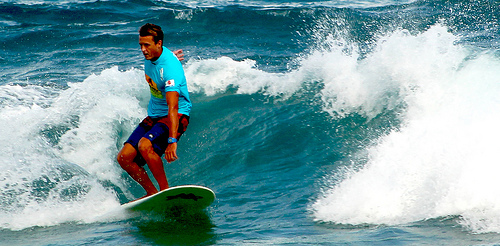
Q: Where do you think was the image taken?
A: It was taken at the ocean.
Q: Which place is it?
A: It is an ocean.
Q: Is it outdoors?
A: Yes, it is outdoors.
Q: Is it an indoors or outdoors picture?
A: It is outdoors.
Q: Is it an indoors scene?
A: No, it is outdoors.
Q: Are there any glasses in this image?
A: No, there are no glasses.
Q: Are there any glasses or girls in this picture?
A: No, there are no glasses or girls.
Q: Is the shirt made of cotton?
A: Yes, the shirt is made of cotton.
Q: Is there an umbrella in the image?
A: No, there are no umbrellas.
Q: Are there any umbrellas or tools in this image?
A: No, there are no umbrellas or tools.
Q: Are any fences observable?
A: No, there are no fences.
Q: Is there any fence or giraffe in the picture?
A: No, there are no fences or giraffes.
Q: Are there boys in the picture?
A: No, there are no boys.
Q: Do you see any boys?
A: No, there are no boys.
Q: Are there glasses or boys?
A: No, there are no boys or glasses.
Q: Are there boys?
A: No, there are no boys.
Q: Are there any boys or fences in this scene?
A: No, there are no boys or fences.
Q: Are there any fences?
A: No, there are no fences.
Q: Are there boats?
A: No, there are no boats.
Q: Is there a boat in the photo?
A: No, there are no boats.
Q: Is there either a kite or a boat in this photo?
A: No, there are no boats or kites.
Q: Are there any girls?
A: No, there are no girls.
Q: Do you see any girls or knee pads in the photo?
A: No, there are no girls or knee pads.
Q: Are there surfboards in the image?
A: Yes, there is a surfboard.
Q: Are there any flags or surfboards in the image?
A: Yes, there is a surfboard.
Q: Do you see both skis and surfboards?
A: No, there is a surfboard but no skis.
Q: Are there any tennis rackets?
A: No, there are no tennis rackets.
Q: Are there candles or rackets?
A: No, there are no rackets or candles.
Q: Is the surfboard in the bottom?
A: Yes, the surfboard is in the bottom of the image.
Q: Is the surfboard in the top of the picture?
A: No, the surfboard is in the bottom of the image.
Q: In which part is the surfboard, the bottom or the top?
A: The surfboard is in the bottom of the image.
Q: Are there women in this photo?
A: No, there are no women.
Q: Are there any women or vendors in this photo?
A: No, there are no women or vendors.